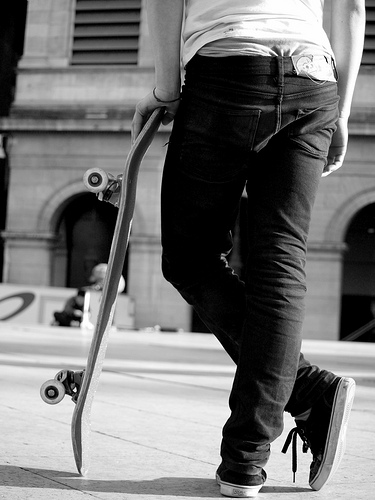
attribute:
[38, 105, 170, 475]
skateboard — upright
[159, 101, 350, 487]
leg — crossed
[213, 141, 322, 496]
leg — crossed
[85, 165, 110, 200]
wheel — white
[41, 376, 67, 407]
wheel — white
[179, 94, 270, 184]
pocket — back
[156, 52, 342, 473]
trousers — black, folded, sagging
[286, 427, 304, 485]
lace — lying, dangling downwards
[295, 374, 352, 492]
shoe — black, white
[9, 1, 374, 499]
photo — white, black, outdoors, daytime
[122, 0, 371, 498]
person — standing, resting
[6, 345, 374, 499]
floor — concrete, grey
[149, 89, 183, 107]
bracelet — black